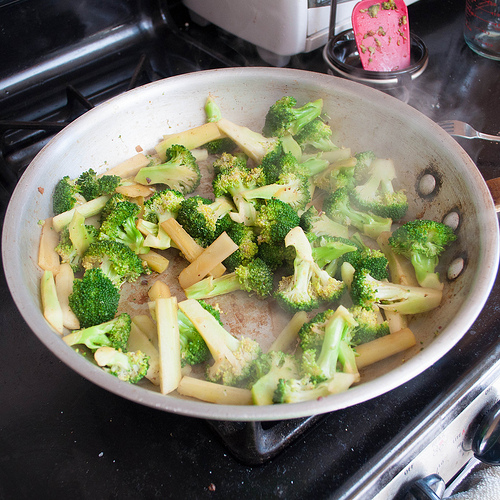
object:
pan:
[0, 65, 499, 423]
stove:
[1, 5, 500, 497]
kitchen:
[2, 0, 499, 499]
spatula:
[348, 0, 413, 76]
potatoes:
[176, 231, 240, 290]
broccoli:
[132, 143, 203, 195]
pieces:
[261, 94, 324, 136]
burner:
[0, 1, 243, 179]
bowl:
[323, 24, 432, 92]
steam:
[307, 39, 482, 232]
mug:
[329, 27, 427, 100]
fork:
[436, 117, 500, 143]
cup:
[434, 7, 499, 119]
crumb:
[206, 482, 216, 492]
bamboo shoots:
[152, 295, 184, 397]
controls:
[470, 398, 500, 468]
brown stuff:
[229, 299, 280, 334]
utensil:
[443, 116, 498, 147]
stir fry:
[36, 92, 455, 407]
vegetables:
[260, 89, 333, 152]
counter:
[3, 3, 499, 499]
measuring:
[462, 5, 499, 30]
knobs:
[467, 400, 500, 470]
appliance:
[183, 0, 419, 72]